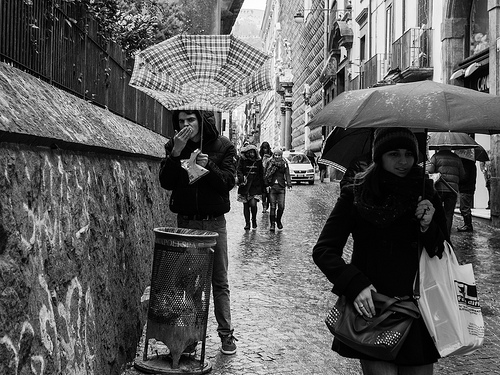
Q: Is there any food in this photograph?
A: Yes, there is food.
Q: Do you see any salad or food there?
A: Yes, there is food.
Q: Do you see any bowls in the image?
A: No, there are no bowls.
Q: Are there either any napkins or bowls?
A: No, there are no bowls or napkins.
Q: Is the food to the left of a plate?
A: No, the food is to the left of a person.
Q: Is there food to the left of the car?
A: Yes, there is food to the left of the car.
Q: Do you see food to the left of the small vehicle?
A: Yes, there is food to the left of the car.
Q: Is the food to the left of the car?
A: Yes, the food is to the left of the car.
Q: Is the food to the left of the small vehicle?
A: Yes, the food is to the left of the car.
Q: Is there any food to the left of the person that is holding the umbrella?
A: Yes, there is food to the left of the person.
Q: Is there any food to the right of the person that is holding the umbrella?
A: No, the food is to the left of the person.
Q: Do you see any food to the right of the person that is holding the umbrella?
A: No, the food is to the left of the person.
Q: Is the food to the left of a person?
A: Yes, the food is to the left of a person.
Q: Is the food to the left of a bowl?
A: No, the food is to the left of a person.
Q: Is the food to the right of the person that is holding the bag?
A: No, the food is to the left of the person.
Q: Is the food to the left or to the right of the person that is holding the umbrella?
A: The food is to the left of the person.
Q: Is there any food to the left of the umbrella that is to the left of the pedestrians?
A: Yes, there is food to the left of the umbrella.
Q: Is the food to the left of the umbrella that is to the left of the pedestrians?
A: Yes, the food is to the left of the umbrella.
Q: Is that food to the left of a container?
A: No, the food is to the left of the umbrella.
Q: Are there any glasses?
A: No, there are no glasses.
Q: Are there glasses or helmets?
A: No, there are no glasses or helmets.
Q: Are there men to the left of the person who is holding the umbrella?
A: Yes, there is a man to the left of the person.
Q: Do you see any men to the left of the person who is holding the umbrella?
A: Yes, there is a man to the left of the person.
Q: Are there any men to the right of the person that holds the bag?
A: No, the man is to the left of the person.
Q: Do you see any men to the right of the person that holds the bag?
A: No, the man is to the left of the person.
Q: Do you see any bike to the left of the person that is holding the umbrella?
A: No, there is a man to the left of the person.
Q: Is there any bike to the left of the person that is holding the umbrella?
A: No, there is a man to the left of the person.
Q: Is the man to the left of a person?
A: Yes, the man is to the left of a person.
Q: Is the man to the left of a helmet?
A: No, the man is to the left of a person.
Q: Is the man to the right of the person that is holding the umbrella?
A: No, the man is to the left of the person.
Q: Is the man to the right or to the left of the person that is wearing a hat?
A: The man is to the left of the person.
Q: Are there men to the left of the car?
A: Yes, there is a man to the left of the car.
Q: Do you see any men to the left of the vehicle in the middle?
A: Yes, there is a man to the left of the car.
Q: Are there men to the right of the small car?
A: No, the man is to the left of the car.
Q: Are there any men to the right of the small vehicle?
A: No, the man is to the left of the car.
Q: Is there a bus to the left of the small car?
A: No, there is a man to the left of the car.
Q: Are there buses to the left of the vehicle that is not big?
A: No, there is a man to the left of the car.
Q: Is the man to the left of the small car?
A: Yes, the man is to the left of the car.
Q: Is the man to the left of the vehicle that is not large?
A: Yes, the man is to the left of the car.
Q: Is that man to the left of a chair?
A: No, the man is to the left of the car.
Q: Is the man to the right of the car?
A: No, the man is to the left of the car.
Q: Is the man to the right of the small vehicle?
A: No, the man is to the left of the car.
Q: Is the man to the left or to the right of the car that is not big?
A: The man is to the left of the car.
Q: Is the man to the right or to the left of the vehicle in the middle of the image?
A: The man is to the left of the car.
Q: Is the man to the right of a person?
A: No, the man is to the left of a person.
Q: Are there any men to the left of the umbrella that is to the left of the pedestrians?
A: Yes, there is a man to the left of the umbrella.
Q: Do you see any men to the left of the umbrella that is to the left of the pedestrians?
A: Yes, there is a man to the left of the umbrella.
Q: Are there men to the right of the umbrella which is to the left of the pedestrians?
A: No, the man is to the left of the umbrella.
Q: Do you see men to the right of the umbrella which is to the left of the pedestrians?
A: No, the man is to the left of the umbrella.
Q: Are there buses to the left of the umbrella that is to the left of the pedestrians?
A: No, there is a man to the left of the umbrella.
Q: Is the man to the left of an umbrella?
A: Yes, the man is to the left of an umbrella.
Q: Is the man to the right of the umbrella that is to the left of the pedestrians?
A: No, the man is to the left of the umbrella.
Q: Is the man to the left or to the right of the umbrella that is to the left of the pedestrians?
A: The man is to the left of the umbrella.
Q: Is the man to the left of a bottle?
A: No, the man is to the left of a person.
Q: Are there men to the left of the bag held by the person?
A: Yes, there is a man to the left of the bag.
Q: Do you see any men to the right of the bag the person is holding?
A: No, the man is to the left of the bag.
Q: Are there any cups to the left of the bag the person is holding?
A: No, there is a man to the left of the bag.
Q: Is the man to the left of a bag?
A: Yes, the man is to the left of a bag.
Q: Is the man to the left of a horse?
A: No, the man is to the left of a bag.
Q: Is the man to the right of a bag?
A: No, the man is to the left of a bag.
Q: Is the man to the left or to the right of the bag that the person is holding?
A: The man is to the left of the bag.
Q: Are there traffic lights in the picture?
A: No, there are no traffic lights.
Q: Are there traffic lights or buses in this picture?
A: No, there are no traffic lights or buses.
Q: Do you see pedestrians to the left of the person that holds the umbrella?
A: Yes, there are pedestrians to the left of the person.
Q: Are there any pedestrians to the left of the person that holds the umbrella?
A: Yes, there are pedestrians to the left of the person.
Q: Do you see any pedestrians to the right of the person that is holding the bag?
A: No, the pedestrians are to the left of the person.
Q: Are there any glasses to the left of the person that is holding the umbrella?
A: No, there are pedestrians to the left of the person.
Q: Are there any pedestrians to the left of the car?
A: Yes, there are pedestrians to the left of the car.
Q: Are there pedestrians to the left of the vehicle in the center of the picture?
A: Yes, there are pedestrians to the left of the car.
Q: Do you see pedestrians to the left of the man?
A: No, the pedestrians are to the right of the man.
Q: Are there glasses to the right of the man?
A: No, there are pedestrians to the right of the man.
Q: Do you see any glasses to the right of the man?
A: No, there are pedestrians to the right of the man.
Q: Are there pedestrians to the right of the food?
A: Yes, there are pedestrians to the right of the food.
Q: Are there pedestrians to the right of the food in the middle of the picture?
A: Yes, there are pedestrians to the right of the food.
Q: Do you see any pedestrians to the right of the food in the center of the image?
A: Yes, there are pedestrians to the right of the food.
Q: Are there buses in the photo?
A: No, there are no buses.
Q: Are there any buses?
A: No, there are no buses.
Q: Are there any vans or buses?
A: No, there are no buses or vans.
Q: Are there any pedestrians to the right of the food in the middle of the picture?
A: Yes, there are pedestrians to the right of the food.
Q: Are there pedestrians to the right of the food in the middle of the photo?
A: Yes, there are pedestrians to the right of the food.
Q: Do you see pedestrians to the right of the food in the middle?
A: Yes, there are pedestrians to the right of the food.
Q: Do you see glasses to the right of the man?
A: No, there are pedestrians to the right of the man.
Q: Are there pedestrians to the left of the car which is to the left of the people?
A: Yes, there are pedestrians to the left of the car.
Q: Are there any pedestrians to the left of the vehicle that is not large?
A: Yes, there are pedestrians to the left of the car.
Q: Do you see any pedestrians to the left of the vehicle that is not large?
A: Yes, there are pedestrians to the left of the car.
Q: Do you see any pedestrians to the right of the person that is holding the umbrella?
A: No, the pedestrians are to the left of the person.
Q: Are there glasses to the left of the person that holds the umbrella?
A: No, there are pedestrians to the left of the person.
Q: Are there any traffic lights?
A: No, there are no traffic lights.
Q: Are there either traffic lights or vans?
A: No, there are no traffic lights or vans.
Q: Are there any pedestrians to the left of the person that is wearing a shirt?
A: Yes, there are pedestrians to the left of the person.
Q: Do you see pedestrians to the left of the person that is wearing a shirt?
A: Yes, there are pedestrians to the left of the person.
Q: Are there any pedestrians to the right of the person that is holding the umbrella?
A: No, the pedestrians are to the left of the person.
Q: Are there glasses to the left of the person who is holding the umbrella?
A: No, there are pedestrians to the left of the person.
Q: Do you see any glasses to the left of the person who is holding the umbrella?
A: No, there are pedestrians to the left of the person.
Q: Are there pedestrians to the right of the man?
A: Yes, there are pedestrians to the right of the man.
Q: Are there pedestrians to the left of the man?
A: No, the pedestrians are to the right of the man.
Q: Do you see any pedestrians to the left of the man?
A: No, the pedestrians are to the right of the man.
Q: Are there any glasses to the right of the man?
A: No, there are pedestrians to the right of the man.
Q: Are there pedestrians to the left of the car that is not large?
A: Yes, there are pedestrians to the left of the car.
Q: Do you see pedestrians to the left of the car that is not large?
A: Yes, there are pedestrians to the left of the car.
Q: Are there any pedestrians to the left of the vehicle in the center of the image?
A: Yes, there are pedestrians to the left of the car.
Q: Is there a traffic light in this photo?
A: No, there are no traffic lights.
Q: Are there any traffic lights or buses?
A: No, there are no traffic lights or buses.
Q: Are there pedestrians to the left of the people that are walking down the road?
A: Yes, there are pedestrians to the left of the people.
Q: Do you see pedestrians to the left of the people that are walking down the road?
A: Yes, there are pedestrians to the left of the people.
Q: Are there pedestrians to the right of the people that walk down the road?
A: No, the pedestrians are to the left of the people.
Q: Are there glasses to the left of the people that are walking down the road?
A: No, there are pedestrians to the left of the people.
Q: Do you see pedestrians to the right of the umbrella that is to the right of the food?
A: Yes, there are pedestrians to the right of the umbrella.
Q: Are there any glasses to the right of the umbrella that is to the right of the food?
A: No, there are pedestrians to the right of the umbrella.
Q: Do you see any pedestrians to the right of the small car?
A: Yes, there are pedestrians to the right of the car.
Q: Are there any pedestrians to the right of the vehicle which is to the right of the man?
A: Yes, there are pedestrians to the right of the car.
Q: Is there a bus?
A: No, there are no buses.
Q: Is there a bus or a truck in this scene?
A: No, there are no buses or trucks.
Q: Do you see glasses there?
A: No, there are no glasses.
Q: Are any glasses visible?
A: No, there are no glasses.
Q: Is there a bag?
A: Yes, there is a bag.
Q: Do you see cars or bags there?
A: Yes, there is a bag.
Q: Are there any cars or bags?
A: Yes, there is a bag.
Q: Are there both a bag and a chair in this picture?
A: No, there is a bag but no chairs.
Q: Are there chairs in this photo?
A: No, there are no chairs.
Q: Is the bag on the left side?
A: No, the bag is on the right of the image.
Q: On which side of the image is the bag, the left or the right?
A: The bag is on the right of the image.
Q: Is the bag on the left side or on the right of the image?
A: The bag is on the right of the image.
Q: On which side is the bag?
A: The bag is on the right of the image.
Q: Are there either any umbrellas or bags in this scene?
A: Yes, there is a bag.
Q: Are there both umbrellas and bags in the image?
A: Yes, there are both a bag and an umbrella.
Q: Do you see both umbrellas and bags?
A: Yes, there are both a bag and an umbrella.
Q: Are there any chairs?
A: No, there are no chairs.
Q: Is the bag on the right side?
A: Yes, the bag is on the right of the image.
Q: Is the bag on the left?
A: No, the bag is on the right of the image.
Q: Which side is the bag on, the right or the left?
A: The bag is on the right of the image.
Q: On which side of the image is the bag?
A: The bag is on the right of the image.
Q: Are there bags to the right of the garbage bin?
A: Yes, there is a bag to the right of the garbage bin.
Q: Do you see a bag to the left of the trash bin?
A: No, the bag is to the right of the trash bin.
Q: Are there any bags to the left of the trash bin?
A: No, the bag is to the right of the trash bin.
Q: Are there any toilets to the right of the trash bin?
A: No, there is a bag to the right of the trash bin.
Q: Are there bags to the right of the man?
A: Yes, there is a bag to the right of the man.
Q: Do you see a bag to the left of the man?
A: No, the bag is to the right of the man.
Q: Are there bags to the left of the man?
A: No, the bag is to the right of the man.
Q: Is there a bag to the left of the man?
A: No, the bag is to the right of the man.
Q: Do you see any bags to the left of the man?
A: No, the bag is to the right of the man.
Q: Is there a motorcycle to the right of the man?
A: No, there is a bag to the right of the man.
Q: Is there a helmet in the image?
A: No, there are no helmets.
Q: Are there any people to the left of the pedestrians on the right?
A: Yes, there is a person to the left of the pedestrians.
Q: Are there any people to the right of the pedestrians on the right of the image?
A: No, the person is to the left of the pedestrians.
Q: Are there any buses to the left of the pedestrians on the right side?
A: No, there is a person to the left of the pedestrians.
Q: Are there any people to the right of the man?
A: Yes, there is a person to the right of the man.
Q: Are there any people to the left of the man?
A: No, the person is to the right of the man.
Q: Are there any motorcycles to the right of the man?
A: No, there is a person to the right of the man.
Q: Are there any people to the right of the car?
A: Yes, there is a person to the right of the car.